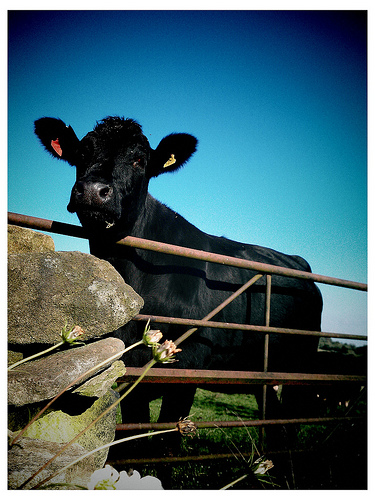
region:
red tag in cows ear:
[36, 124, 73, 171]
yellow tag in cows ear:
[154, 144, 182, 186]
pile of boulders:
[15, 246, 123, 488]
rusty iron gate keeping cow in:
[8, 204, 362, 489]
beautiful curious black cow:
[28, 93, 323, 453]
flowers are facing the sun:
[26, 310, 177, 436]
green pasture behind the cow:
[124, 372, 350, 480]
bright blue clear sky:
[14, 14, 373, 266]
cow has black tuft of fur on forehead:
[97, 107, 139, 138]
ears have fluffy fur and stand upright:
[22, 100, 229, 196]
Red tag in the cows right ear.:
[49, 137, 62, 160]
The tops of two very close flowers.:
[143, 316, 176, 364]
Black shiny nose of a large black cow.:
[71, 179, 114, 207]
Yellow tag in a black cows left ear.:
[160, 153, 176, 168]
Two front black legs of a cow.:
[114, 380, 197, 446]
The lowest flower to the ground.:
[217, 456, 276, 490]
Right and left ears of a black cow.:
[34, 117, 199, 175]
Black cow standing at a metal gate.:
[32, 116, 322, 452]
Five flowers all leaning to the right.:
[7, 316, 273, 488]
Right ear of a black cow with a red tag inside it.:
[33, 114, 79, 163]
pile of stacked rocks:
[8, 221, 131, 491]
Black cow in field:
[37, 115, 340, 495]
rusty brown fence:
[130, 246, 374, 488]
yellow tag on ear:
[155, 148, 183, 172]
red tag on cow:
[39, 128, 75, 162]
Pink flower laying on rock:
[4, 321, 88, 369]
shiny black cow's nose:
[70, 175, 112, 205]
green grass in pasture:
[198, 391, 253, 446]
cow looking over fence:
[30, 101, 192, 255]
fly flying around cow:
[145, 124, 156, 140]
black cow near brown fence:
[32, 91, 335, 440]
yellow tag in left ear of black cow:
[151, 132, 200, 194]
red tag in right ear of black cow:
[35, 103, 77, 180]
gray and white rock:
[19, 233, 141, 326]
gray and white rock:
[10, 349, 123, 435]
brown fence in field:
[261, 368, 356, 459]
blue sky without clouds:
[22, 24, 184, 110]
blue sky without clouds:
[113, 18, 332, 112]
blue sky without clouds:
[205, 65, 268, 229]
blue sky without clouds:
[274, 52, 361, 234]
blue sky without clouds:
[210, 37, 303, 218]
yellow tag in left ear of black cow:
[155, 128, 191, 176]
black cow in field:
[21, 93, 341, 437]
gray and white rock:
[16, 396, 115, 473]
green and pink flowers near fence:
[132, 311, 184, 390]